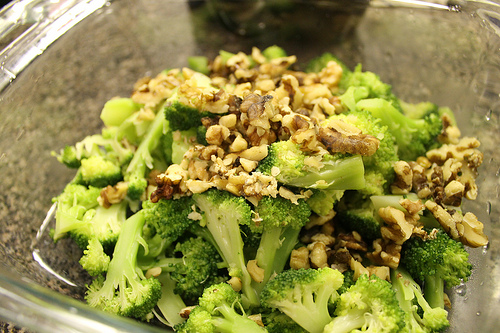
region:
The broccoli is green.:
[356, 90, 437, 154]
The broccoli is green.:
[250, 133, 372, 203]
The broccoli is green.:
[401, 220, 469, 322]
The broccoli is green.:
[312, 271, 409, 331]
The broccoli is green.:
[258, 252, 348, 332]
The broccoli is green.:
[174, 277, 271, 332]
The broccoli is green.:
[252, 195, 309, 304]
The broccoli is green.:
[193, 186, 253, 290]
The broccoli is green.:
[77, 205, 164, 317]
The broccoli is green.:
[68, 181, 126, 256]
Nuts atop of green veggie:
[136, 161, 190, 203]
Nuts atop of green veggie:
[188, 154, 221, 193]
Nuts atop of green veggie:
[219, 155, 277, 195]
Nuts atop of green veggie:
[207, 130, 272, 158]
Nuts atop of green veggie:
[265, 108, 325, 161]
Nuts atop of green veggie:
[296, 68, 336, 125]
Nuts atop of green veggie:
[290, 226, 351, 286]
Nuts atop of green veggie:
[332, 211, 411, 287]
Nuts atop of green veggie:
[370, 165, 435, 251]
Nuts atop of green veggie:
[387, 128, 496, 251]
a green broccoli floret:
[330, 272, 406, 332]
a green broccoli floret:
[268, 266, 331, 331]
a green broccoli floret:
[183, 280, 263, 331]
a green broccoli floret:
[81, 224, 168, 311]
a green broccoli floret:
[193, 179, 250, 277]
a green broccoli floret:
[248, 194, 311, 275]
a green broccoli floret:
[404, 234, 473, 313]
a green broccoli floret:
[263, 148, 365, 188]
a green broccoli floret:
[69, 140, 117, 182]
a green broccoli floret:
[358, 92, 440, 160]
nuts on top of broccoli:
[116, 42, 399, 229]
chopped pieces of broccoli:
[105, 47, 458, 324]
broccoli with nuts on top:
[83, 67, 485, 309]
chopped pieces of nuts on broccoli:
[140, 35, 477, 265]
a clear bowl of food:
[19, 3, 496, 307]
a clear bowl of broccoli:
[8, 22, 493, 332]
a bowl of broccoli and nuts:
[24, 30, 424, 330]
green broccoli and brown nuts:
[66, 52, 403, 331]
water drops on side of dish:
[449, 63, 499, 313]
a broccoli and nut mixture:
[103, 87, 370, 305]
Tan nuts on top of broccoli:
[140, 52, 340, 203]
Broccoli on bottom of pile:
[258, 269, 340, 322]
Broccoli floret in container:
[92, 213, 159, 312]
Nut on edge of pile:
[460, 210, 486, 249]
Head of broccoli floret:
[164, 238, 216, 294]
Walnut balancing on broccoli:
[327, 122, 375, 152]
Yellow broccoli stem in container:
[207, 217, 252, 285]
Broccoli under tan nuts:
[418, 231, 466, 303]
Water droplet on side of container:
[452, 280, 470, 296]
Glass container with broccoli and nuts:
[2, 4, 495, 331]